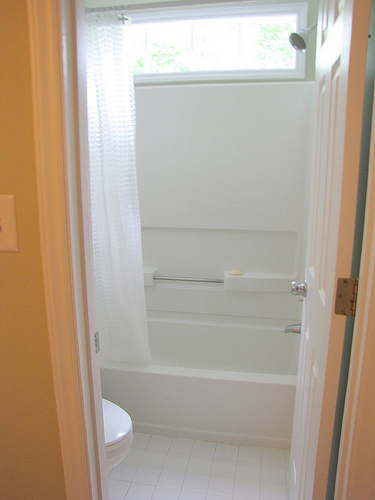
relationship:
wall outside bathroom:
[0, 0, 64, 498] [85, 0, 312, 498]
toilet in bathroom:
[99, 396, 134, 481] [85, 0, 312, 498]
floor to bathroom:
[103, 428, 287, 497] [5, 3, 352, 493]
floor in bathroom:
[103, 428, 287, 497] [85, 0, 312, 498]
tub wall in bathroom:
[126, 361, 287, 446] [85, 0, 312, 498]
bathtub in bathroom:
[102, 309, 298, 447] [86, 0, 338, 494]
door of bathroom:
[276, 1, 358, 498] [85, 0, 312, 498]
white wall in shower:
[150, 91, 294, 226] [100, 1, 318, 447]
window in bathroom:
[135, 3, 306, 89] [85, 0, 312, 498]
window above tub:
[135, 3, 306, 89] [104, 315, 299, 443]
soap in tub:
[227, 268, 243, 276] [105, 310, 288, 447]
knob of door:
[287, 278, 309, 297] [276, 1, 358, 498]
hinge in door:
[334, 276, 354, 316] [276, 1, 358, 498]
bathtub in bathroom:
[102, 309, 298, 447] [85, 0, 312, 498]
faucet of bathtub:
[281, 322, 297, 339] [102, 309, 298, 447]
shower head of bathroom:
[289, 21, 317, 55] [85, 0, 312, 498]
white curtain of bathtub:
[79, 9, 153, 364] [102, 309, 298, 447]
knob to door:
[287, 278, 309, 297] [276, 1, 358, 498]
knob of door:
[287, 278, 309, 297] [273, 3, 364, 498]